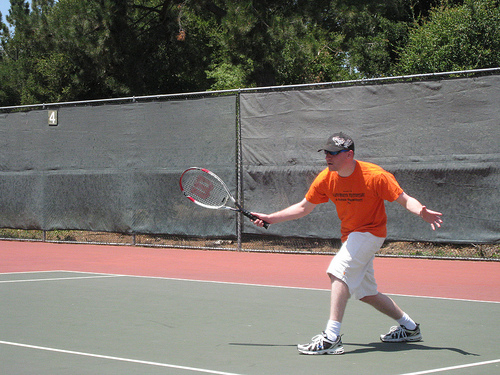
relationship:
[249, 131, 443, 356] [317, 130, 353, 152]
man wearing cap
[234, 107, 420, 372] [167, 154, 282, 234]
man holding racket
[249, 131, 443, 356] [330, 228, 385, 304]
man wearing white shorts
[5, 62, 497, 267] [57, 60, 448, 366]
fence around tennis court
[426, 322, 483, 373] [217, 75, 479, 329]
shadow of man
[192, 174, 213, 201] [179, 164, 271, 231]
logo of racket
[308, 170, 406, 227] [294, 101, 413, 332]
shirt of man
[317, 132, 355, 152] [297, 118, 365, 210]
cap on man's head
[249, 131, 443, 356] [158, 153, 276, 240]
man holding racket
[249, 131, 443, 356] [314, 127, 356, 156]
man wearing hat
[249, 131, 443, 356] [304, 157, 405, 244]
man wearing shirt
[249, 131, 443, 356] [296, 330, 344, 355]
man wearing shoe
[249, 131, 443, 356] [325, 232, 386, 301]
man wearing shorts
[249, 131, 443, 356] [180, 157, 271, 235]
man carrying racket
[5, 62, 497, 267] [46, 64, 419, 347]
fence in tennis court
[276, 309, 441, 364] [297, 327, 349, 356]
sneaker with stripes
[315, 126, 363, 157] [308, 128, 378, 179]
cap with sun visor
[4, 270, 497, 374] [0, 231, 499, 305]
tennis court with border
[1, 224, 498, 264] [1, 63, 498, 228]
dirt beneath fence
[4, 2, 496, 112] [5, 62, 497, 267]
trees behind fence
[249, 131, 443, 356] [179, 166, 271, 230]
man holds racket